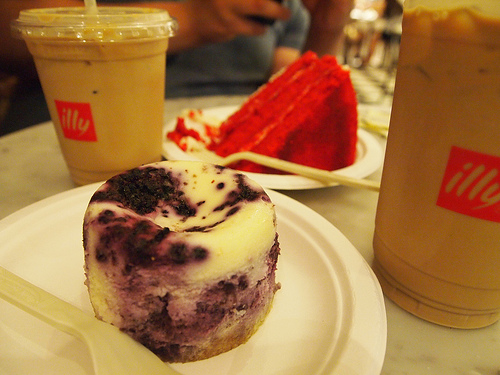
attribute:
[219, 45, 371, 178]
cake — red velvet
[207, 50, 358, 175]
cake slice — large, red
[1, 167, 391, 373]
plate — white, round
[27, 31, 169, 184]
coffee — iced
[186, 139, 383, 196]
fork — cream colored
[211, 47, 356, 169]
cake — red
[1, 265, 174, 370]
fork — cream colored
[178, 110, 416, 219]
plate — white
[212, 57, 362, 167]
cake — red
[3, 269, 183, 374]
fork — plastic, white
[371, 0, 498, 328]
cup — plastic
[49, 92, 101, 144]
logo — red, fully visible, square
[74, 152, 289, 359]
dessert — purple and white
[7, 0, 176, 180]
cup — plastic, clear, fully visible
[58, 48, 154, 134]
liquid — brown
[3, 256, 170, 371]
utensil — cream colored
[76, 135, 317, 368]
dessert — purple and white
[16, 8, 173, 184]
cup — plastic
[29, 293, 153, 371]
fork — plastic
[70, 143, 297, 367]
dessert — purple and white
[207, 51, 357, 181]
velvet cake — red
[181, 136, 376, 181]
fork — white, plastic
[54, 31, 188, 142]
coffee — iced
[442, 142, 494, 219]
square logo — red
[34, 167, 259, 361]
plate — white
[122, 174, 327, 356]
dessert — purplish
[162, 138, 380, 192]
fork — white, plastic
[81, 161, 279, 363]
dessert — purple and white, round, purple